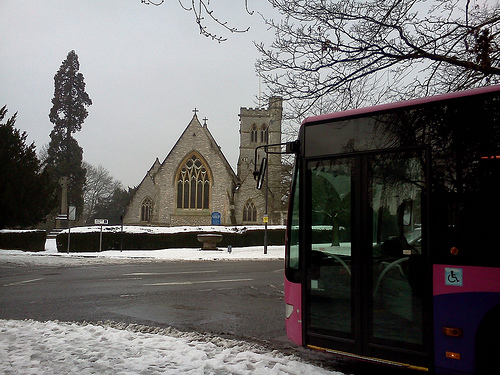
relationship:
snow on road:
[6, 227, 429, 371] [2, 253, 305, 374]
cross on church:
[191, 106, 200, 115] [106, 96, 298, 229]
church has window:
[106, 96, 298, 229] [175, 150, 213, 209]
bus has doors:
[282, 80, 497, 374] [300, 150, 433, 374]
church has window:
[106, 96, 298, 229] [249, 125, 258, 146]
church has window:
[106, 96, 298, 229] [258, 124, 267, 144]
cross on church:
[202, 115, 208, 123] [106, 96, 298, 229]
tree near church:
[50, 48, 89, 231] [106, 96, 298, 229]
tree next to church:
[45, 48, 90, 231] [106, 96, 298, 229]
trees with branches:
[452, 6, 499, 83] [300, 16, 443, 73]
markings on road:
[126, 265, 256, 292] [2, 253, 305, 374]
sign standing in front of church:
[212, 210, 227, 226] [106, 96, 298, 229]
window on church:
[177, 152, 212, 209] [106, 96, 298, 229]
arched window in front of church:
[173, 148, 213, 214] [106, 96, 298, 229]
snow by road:
[104, 342, 157, 373] [151, 282, 218, 323]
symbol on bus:
[444, 266, 464, 286] [282, 80, 497, 374]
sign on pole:
[260, 210, 277, 233] [252, 142, 293, 287]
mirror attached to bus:
[242, 140, 287, 192] [285, 94, 485, 373]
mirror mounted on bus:
[242, 140, 287, 192] [285, 94, 485, 373]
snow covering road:
[0, 318, 325, 371] [2, 253, 305, 374]